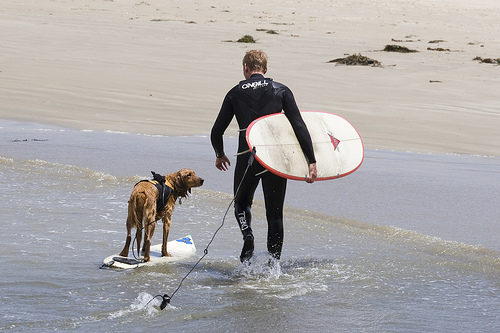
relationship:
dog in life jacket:
[120, 167, 205, 259] [147, 168, 174, 212]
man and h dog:
[210, 49, 316, 269] [120, 167, 205, 259]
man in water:
[210, 49, 316, 269] [5, 123, 496, 331]